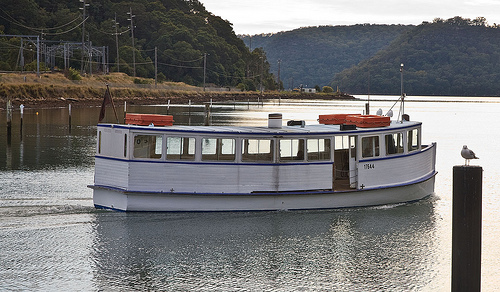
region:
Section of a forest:
[334, 54, 401, 89]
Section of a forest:
[280, 30, 340, 76]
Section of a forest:
[360, 27, 446, 64]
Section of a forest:
[431, 35, 483, 92]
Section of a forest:
[189, 17, 243, 54]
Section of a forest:
[137, 8, 189, 65]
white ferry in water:
[97, 89, 428, 216]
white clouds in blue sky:
[340, 9, 404, 34]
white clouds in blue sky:
[441, 1, 473, 27]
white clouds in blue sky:
[172, 8, 218, 30]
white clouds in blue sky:
[172, 1, 229, 26]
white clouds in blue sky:
[226, 4, 272, 31]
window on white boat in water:
[133, 136, 164, 158]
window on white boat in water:
[165, 137, 196, 161]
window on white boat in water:
[202, 139, 235, 160]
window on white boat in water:
[242, 137, 273, 162]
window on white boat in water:
[281, 140, 306, 161]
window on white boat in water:
[306, 138, 332, 160]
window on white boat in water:
[361, 134, 381, 157]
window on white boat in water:
[385, 131, 405, 155]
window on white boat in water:
[407, 126, 419, 151]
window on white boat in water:
[156, 135, 183, 154]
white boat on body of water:
[82, 109, 440, 225]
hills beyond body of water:
[1, 1, 498, 109]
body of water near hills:
[4, 87, 499, 290]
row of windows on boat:
[127, 120, 423, 165]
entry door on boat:
[330, 130, 360, 195]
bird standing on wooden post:
[454, 140, 480, 175]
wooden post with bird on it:
[445, 141, 485, 290]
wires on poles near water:
[3, 2, 140, 43]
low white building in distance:
[299, 84, 318, 96]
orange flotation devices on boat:
[120, 109, 393, 134]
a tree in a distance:
[179, 21, 202, 79]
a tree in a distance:
[198, 53, 219, 99]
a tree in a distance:
[204, 35, 227, 55]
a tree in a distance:
[58, 13, 88, 43]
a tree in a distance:
[154, 14, 185, 34]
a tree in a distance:
[247, 37, 276, 87]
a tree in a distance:
[45, 8, 84, 38]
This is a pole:
[191, 46, 216, 91]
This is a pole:
[146, 40, 164, 82]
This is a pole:
[270, 52, 290, 94]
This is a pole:
[234, 50, 264, 104]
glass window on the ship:
[132, 133, 164, 158]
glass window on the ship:
[167, 135, 197, 160]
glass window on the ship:
[199, 135, 236, 160]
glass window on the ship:
[240, 135, 272, 162]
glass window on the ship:
[276, 135, 302, 160]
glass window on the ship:
[307, 137, 333, 162]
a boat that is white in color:
[105, 71, 470, 235]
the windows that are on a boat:
[142, 125, 343, 177]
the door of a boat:
[320, 121, 372, 193]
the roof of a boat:
[144, 96, 409, 141]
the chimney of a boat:
[271, 102, 292, 144]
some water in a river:
[75, 222, 269, 290]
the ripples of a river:
[240, 228, 304, 266]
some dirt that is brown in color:
[37, 69, 118, 96]